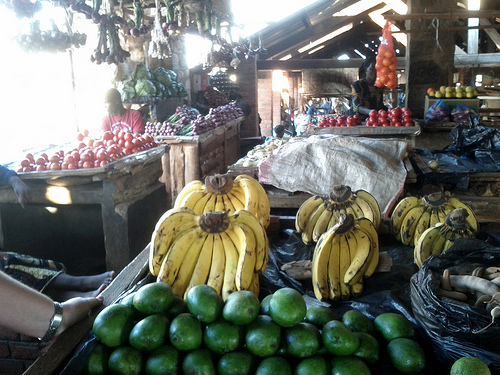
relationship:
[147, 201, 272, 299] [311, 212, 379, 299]
bananas by bananas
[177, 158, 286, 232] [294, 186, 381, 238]
banana by bananas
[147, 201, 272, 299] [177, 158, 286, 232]
bananas by banana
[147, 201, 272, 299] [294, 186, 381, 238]
bananas by bananas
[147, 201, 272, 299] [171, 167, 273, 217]
bananas by bananas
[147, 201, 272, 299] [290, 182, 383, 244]
bananas by bananas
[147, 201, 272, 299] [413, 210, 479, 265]
bananas by bananas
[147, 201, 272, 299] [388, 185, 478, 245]
bananas by bananas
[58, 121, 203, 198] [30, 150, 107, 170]
apples stacked on apples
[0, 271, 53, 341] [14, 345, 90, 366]
arm leaning on shelf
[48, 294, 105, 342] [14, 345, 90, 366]
hand leaning on shelf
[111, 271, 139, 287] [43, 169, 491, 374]
shelf for fruit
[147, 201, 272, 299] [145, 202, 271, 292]
bananas in bunch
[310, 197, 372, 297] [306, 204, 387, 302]
bananas in bunch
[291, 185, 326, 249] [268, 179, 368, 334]
bananas on a cart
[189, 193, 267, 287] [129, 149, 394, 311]
banana on cart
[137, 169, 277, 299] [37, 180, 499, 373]
bananas on cart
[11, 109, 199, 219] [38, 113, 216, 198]
crate of food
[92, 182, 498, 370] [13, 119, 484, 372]
produce displaying its wares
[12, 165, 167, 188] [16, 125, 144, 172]
bin of tomatoes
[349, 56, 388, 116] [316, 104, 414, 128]
buyer looking at goods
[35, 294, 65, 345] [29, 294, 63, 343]
watch around a wrist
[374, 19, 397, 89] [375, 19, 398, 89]
bag hanging oranges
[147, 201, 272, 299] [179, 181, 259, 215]
bananas in a bananas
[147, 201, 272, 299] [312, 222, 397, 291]
bananas in a bunch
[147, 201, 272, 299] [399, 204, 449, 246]
bananas in a bunch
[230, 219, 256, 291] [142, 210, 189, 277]
banana on a banana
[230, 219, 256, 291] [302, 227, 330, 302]
banana on a banana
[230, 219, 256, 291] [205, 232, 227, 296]
banana on a banana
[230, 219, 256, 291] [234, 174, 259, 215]
banana on a banana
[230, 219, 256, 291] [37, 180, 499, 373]
banana on a cart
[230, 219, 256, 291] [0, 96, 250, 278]
banana on a cart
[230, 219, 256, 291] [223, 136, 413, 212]
banana on a cart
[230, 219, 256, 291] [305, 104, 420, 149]
banana on a cart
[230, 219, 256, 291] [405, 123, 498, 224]
banana on a cart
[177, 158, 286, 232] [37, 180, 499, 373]
banana on a cart